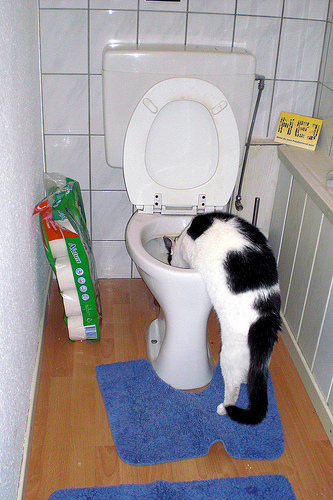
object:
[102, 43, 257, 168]
tank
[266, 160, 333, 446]
wall boards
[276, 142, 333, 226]
shelf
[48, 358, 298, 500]
rugs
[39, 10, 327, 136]
tiles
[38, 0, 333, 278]
wall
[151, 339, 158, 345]
screw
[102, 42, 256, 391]
toilet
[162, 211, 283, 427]
cat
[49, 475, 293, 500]
mat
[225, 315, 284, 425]
tail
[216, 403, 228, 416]
paw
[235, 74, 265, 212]
metal pipe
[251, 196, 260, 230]
handle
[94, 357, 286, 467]
blue rug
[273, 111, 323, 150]
card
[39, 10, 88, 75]
tile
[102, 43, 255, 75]
lid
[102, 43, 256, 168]
toilet tank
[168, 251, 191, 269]
face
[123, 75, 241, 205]
lid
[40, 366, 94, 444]
design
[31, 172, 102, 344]
pack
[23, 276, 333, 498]
floor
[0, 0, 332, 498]
bathroom